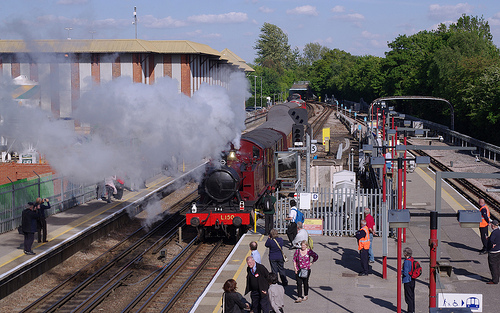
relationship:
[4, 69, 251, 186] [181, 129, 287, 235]
smoke coming from train engine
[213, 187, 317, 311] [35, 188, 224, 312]
people by train tracks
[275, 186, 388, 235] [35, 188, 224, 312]
fence by train tracks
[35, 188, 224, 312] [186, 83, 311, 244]
train tracks for train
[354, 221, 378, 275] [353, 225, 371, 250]
man in orange vest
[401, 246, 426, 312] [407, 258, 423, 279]
man has red backpack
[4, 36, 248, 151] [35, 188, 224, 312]
building near train tracks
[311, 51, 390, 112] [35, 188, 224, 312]
trees by train tracks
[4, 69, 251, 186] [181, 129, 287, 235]
smoke from train engine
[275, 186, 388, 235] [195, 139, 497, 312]
fence on platform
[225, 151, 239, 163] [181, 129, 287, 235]
bell on train engine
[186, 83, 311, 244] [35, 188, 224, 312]
train on train tracks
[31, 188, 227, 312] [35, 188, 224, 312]
train tracks next train tracks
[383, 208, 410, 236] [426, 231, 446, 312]
light on light pole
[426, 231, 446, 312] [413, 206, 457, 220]
light pole has arm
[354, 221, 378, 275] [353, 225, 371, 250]
man wearing orange vest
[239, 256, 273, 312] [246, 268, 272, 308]
man in a suit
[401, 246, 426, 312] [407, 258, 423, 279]
man with backpack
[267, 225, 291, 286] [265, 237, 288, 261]
woman wearing a shirt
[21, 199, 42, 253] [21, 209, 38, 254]
man in a suit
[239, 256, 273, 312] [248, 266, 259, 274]
man wearing shirt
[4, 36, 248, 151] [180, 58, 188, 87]
building made from brick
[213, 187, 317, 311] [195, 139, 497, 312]
people on platform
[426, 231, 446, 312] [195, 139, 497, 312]
light pole on platform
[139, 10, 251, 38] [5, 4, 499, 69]
clouds in sky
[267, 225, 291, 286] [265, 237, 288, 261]
woman in shirt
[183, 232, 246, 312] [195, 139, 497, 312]
stripe on platform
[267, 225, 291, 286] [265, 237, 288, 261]
woman wearing shirt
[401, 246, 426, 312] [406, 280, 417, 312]
man wearing pants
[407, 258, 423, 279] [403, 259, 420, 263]
backpack around shoulders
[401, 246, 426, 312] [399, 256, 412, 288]
man wearing shirt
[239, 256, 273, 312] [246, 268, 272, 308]
man wearing suit